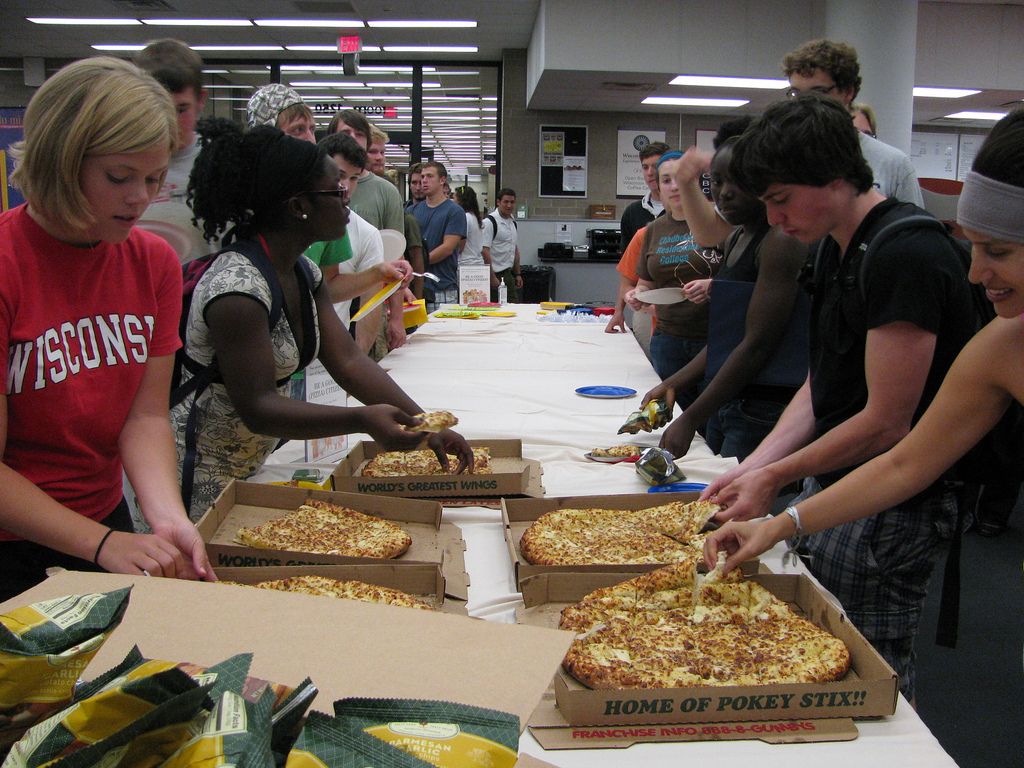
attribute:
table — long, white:
[169, 280, 962, 764]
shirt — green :
[295, 222, 352, 272]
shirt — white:
[475, 212, 521, 271]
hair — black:
[188, 115, 323, 230]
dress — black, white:
[154, 254, 336, 555]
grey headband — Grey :
[948, 150, 1016, 244]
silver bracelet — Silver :
[786, 487, 808, 570]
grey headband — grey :
[950, 141, 1017, 228]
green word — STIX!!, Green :
[788, 681, 892, 708]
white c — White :
[56, 320, 89, 375]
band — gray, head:
[947, 161, 991, 239]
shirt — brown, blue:
[633, 219, 718, 315]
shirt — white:
[482, 215, 528, 283]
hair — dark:
[774, 122, 844, 162]